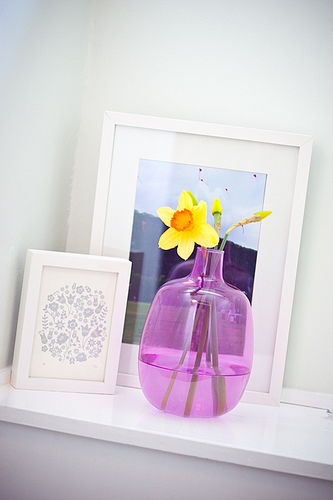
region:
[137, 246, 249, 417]
a transparent pink jar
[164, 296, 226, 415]
the flower stems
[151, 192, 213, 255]
a yellow flower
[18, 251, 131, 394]
a white frame with many figures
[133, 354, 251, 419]
some water in the jar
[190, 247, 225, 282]
the neck of the jar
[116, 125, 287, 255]
the sky on the in the frame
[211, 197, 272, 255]
two yellow buds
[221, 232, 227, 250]
one green bud stem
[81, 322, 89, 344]
a flower figure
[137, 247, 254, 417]
a pink glass flower vase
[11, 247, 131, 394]
a framed arts and craft drawing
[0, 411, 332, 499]
a bedroom dresser counter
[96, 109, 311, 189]
a framed picture of artwork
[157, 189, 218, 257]
an artificial flower and vase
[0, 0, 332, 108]
a light green wall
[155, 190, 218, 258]
a yellow artificial silk flower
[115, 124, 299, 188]
a matted picture frame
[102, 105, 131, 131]
a white metal picture frame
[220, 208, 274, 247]
an artificial flower bud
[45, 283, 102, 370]
Floral picture design in frame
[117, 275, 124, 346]
Right side of white picture frame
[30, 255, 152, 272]
Top of white picture frame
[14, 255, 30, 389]
Left side of white picture frame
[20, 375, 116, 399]
Bottom of white picture frame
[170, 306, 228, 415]
Green flower stems in water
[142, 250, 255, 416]
Bright pink flower vase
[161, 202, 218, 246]
Yellow sun flower in vase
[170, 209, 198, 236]
Orange flower bud on yellow flower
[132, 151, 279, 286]
Nature painting in photo frame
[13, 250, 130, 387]
A white picture frame on the mantle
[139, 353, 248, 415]
Water in the vase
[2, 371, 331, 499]
A mantle holding a few items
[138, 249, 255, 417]
A pink vase holding a flower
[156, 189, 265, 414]
A blooming flower in the vase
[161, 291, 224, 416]
The stems of the flowers in water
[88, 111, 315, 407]
A picture behind the vase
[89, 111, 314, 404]
The picture frame is white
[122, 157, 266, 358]
The picture includes mountains, kites, and people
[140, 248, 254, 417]
The pink vase contains water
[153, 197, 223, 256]
The flower in the vase.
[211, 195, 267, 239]
The two flowers that haven't bloomed.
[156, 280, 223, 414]
The stems in the purple vase.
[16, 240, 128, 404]
The frame on the shelf with a flower design picture.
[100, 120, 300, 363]
The frame behind the vase.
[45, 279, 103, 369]
The flower design art in the frame.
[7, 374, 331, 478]
The white shelf the items are placed on.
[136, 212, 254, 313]
The hill in the photo behind the vase.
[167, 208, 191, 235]
The center of the flower in the vase.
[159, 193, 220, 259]
The petals of the flower in the vase.